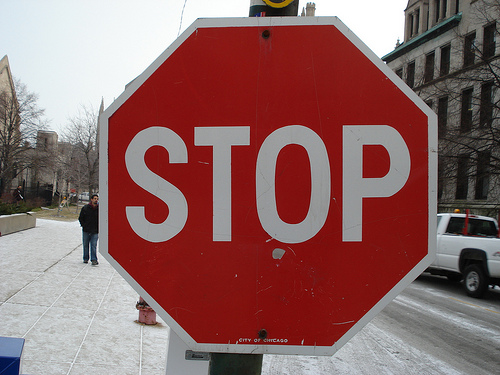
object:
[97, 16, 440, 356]
sign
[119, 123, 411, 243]
stop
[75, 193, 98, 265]
man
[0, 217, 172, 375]
sidewalk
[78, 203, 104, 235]
jacket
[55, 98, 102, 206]
tree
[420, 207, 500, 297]
truck